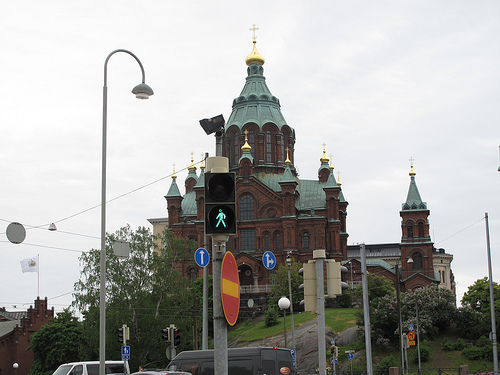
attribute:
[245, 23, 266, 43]
cross — white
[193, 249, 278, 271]
signs — blue, round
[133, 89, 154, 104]
light — white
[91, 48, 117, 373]
pole — metal, curved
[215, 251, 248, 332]
sign — red/yellow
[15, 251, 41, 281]
flag — white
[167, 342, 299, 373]
van — black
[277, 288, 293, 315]
lamp — white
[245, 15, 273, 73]
steeple — large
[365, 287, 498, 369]
shrubbery — green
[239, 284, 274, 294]
railing — white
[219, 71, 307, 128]
roofing — green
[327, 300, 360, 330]
grass — green